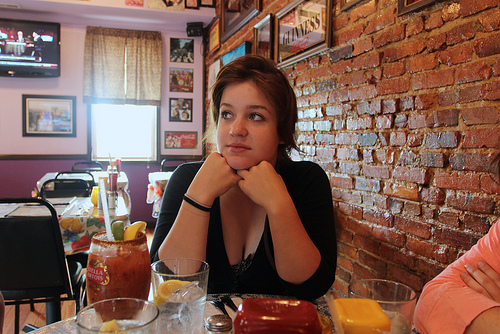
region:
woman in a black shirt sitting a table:
[151, 54, 335, 299]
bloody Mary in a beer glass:
[87, 230, 150, 320]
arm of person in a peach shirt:
[417, 203, 499, 331]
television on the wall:
[2, 20, 64, 77]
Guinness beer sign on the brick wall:
[277, 8, 330, 59]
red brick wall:
[206, 0, 498, 295]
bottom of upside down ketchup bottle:
[237, 300, 313, 332]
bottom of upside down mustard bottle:
[338, 295, 388, 330]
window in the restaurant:
[87, 28, 162, 163]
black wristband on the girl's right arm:
[180, 192, 211, 217]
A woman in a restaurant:
[1, 2, 404, 332]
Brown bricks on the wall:
[270, 1, 498, 313]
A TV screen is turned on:
[1, 16, 63, 80]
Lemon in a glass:
[152, 273, 197, 312]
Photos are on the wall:
[161, 33, 201, 152]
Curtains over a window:
[78, 23, 168, 111]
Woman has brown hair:
[206, 50, 306, 170]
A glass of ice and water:
[148, 253, 210, 331]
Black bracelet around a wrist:
[178, 189, 216, 215]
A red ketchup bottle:
[230, 295, 322, 332]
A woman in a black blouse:
[153, 53, 342, 298]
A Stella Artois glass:
[84, 227, 152, 327]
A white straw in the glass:
[94, 175, 118, 238]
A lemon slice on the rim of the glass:
[123, 218, 148, 243]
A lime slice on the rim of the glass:
[110, 216, 122, 238]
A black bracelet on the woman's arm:
[179, 191, 215, 216]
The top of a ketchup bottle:
[227, 294, 325, 332]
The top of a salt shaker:
[204, 312, 234, 332]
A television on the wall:
[0, 16, 65, 80]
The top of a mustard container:
[331, 294, 391, 332]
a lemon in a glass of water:
[143, 270, 193, 311]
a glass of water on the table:
[138, 252, 218, 332]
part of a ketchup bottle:
[229, 289, 323, 329]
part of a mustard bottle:
[321, 291, 401, 332]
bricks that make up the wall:
[353, 43, 498, 166]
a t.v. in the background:
[0, 10, 70, 87]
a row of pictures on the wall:
[163, 30, 197, 129]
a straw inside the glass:
[90, 167, 123, 242]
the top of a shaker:
[196, 302, 237, 328]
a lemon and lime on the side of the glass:
[102, 212, 147, 247]